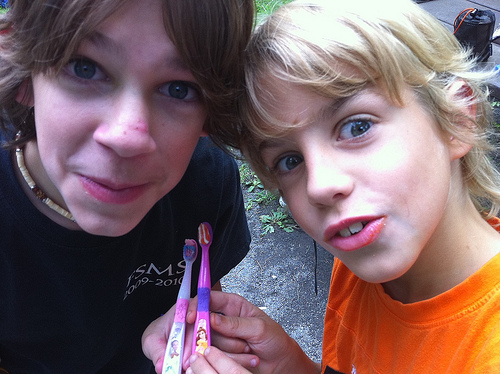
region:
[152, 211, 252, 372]
two girly pink and purple toothbrushes held by two boys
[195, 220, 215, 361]
pink toothbrush with Disney princess Belle from Beauty and the Beast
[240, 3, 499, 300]
boy with blonde short hair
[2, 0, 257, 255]
boy with brown hair looking at camera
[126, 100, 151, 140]
a pimple from a young boy with brown hair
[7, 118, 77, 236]
boy with brown boy is wearing beaded necklace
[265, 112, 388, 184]
boy with blonde hair has green eyes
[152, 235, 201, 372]
purple toothbrush with frog princess from disney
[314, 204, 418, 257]
boy showing his two front teeth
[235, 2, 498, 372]
boy with blonde hair is wearing an orange shirt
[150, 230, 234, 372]
the tooth brush are two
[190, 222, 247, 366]
the truth brush is purple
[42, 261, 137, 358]
his shirt is black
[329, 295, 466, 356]
the shirt is orange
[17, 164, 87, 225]
he has a neckace on his neck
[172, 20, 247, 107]
his hair is dark brown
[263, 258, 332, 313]
the pavement is grey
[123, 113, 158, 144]
he has a red spot on the nose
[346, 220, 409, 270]
his teeth are White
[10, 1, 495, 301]
two little boys posing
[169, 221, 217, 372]
disney princess toothbrushes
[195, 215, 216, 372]
belle from beauty and the beast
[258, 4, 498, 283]
blonde haired boy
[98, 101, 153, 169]
imperfection on boy's nose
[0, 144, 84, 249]
boy wearing necklace made of shells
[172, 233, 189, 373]
disney frozen purple toothbrush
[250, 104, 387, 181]
boy with blue eyes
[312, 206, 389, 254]
boy with buck teeth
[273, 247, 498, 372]
boy wearing orange shirt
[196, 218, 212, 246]
red and white toothbrush bristles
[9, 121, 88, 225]
a white and brown necklace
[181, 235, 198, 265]
blue and pink toothbrush bristles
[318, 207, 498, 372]
an orange tee shirt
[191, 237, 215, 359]
a pink and blue toothbrush handle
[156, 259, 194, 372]
a blue and pink toothbrush handle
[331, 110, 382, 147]
the eye of a child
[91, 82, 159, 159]
the nose of a child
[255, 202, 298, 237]
plants on the ground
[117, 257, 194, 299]
white writing on a tee shirt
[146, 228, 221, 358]
Two tooth brush are seen.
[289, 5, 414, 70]
hair color is tan.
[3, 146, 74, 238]
Necklace is seen in the boy neck.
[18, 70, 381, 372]
Two boys are holding the toothbrush.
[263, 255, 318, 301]
Wall is grey color.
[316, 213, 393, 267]
Boy two upper front teeth is seen.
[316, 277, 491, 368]
Boy is wearing orange shirt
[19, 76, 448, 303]
Day time picture.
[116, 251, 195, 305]
Letters are white color in shirt.